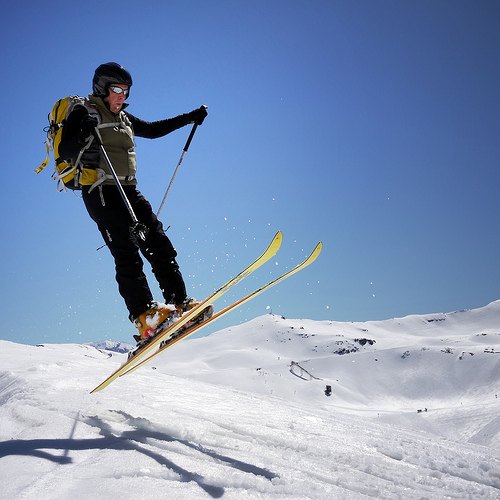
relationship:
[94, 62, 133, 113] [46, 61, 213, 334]
head of man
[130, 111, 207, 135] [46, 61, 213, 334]
arm of man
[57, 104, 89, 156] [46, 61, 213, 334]
arm of man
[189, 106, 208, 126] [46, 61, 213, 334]
hand of man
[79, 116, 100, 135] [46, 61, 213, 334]
hand of man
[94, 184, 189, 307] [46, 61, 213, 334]
legs of man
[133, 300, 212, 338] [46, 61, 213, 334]
shoes of man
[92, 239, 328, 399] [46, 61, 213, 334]
skis of man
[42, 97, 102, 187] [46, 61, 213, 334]
backpack of man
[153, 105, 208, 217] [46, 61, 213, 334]
pole of man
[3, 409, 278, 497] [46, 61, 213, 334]
shadow of man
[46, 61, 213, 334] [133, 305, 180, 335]
man wearing boot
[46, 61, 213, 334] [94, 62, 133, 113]
man with head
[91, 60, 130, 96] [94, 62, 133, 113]
helmet on top of head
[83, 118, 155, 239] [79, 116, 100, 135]
pole in palm of hand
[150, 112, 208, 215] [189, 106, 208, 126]
pole in palm of hand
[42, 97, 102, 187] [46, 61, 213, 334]
backpack on back of man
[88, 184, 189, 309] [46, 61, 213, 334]
pants on bottom of man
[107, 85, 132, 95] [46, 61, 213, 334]
goggles on face of man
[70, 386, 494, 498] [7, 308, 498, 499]
trails through snow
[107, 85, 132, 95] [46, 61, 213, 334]
goggles of man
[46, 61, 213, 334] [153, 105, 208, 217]
man holding pole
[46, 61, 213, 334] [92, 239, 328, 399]
man jumping on skis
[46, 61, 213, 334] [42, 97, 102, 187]
man wearing backpack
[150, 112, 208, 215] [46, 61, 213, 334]
pole of man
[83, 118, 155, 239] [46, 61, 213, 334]
pole of man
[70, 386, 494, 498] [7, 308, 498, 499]
trails in snow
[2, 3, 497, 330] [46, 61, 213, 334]
sky behind man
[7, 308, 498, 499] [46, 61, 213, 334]
snow behind man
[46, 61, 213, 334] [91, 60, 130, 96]
man with helmet